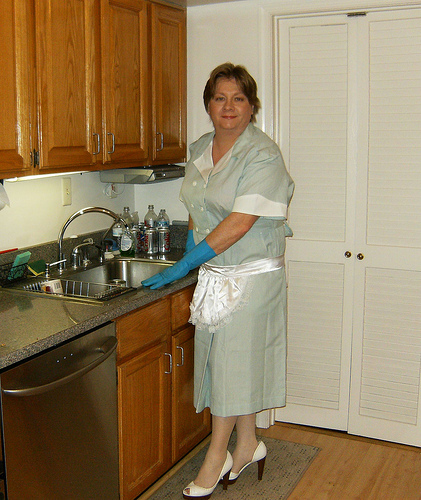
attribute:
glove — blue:
[141, 240, 215, 288]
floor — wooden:
[140, 424, 419, 496]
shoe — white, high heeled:
[193, 460, 232, 494]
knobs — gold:
[340, 244, 374, 266]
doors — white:
[268, 33, 417, 446]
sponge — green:
[3, 251, 34, 285]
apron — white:
[185, 249, 288, 334]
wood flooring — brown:
[332, 452, 380, 479]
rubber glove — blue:
[181, 224, 197, 248]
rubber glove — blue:
[143, 239, 218, 296]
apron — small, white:
[186, 252, 282, 332]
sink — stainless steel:
[35, 261, 170, 303]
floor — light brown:
[318, 447, 396, 498]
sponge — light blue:
[6, 248, 28, 276]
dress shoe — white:
[179, 479, 208, 497]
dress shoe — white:
[250, 442, 268, 461]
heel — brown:
[221, 469, 230, 490]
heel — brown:
[253, 457, 269, 484]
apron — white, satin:
[185, 257, 286, 333]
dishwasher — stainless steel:
[1, 344, 153, 466]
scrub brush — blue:
[103, 235, 124, 263]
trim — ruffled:
[186, 273, 250, 332]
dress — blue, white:
[175, 124, 295, 416]